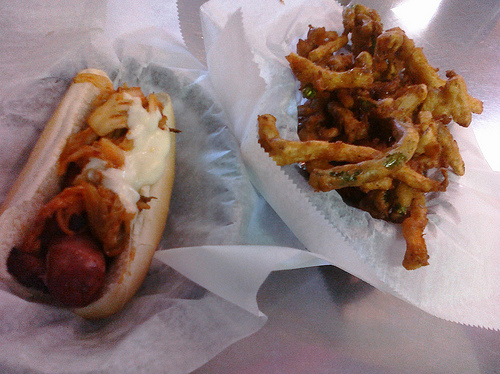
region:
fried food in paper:
[266, 2, 474, 273]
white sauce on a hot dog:
[87, 87, 181, 209]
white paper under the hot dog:
[190, 214, 311, 331]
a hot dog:
[6, 212, 114, 318]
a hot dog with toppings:
[0, 60, 155, 345]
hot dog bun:
[0, 55, 122, 283]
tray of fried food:
[201, 2, 489, 294]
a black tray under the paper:
[0, 36, 257, 353]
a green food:
[329, 147, 404, 192]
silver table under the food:
[278, 281, 383, 368]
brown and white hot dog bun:
[0, 67, 176, 318]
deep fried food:
[252, 1, 482, 266]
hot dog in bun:
[42, 82, 147, 302]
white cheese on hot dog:
[81, 90, 168, 210]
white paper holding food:
[0, 0, 497, 370]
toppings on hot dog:
[25, 70, 170, 310]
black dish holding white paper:
[20, 55, 235, 340]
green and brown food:
[250, 0, 480, 265]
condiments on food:
[20, 70, 165, 305]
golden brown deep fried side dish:
[255, 1, 485, 271]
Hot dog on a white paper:
[6, 60, 185, 342]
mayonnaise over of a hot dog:
[102, 96, 176, 210]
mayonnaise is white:
[111, 101, 175, 201]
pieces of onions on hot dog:
[66, 69, 136, 159]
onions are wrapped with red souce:
[57, 64, 130, 255]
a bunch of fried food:
[250, 0, 475, 277]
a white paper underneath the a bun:
[0, 7, 268, 359]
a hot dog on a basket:
[11, 51, 250, 344]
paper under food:
[193, 0, 498, 340]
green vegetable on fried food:
[374, 139, 413, 179]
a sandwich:
[22, 42, 194, 356]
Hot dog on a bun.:
[3, 44, 173, 341]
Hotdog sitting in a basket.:
[9, 54, 268, 359]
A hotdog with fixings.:
[1, 62, 185, 362]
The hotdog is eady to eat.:
[6, 60, 242, 350]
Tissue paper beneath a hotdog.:
[2, 0, 287, 372]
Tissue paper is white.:
[1, 1, 271, 371]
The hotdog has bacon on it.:
[3, 50, 181, 345]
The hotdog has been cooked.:
[0, 45, 193, 332]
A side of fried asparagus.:
[231, 2, 497, 296]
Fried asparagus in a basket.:
[213, 5, 498, 302]